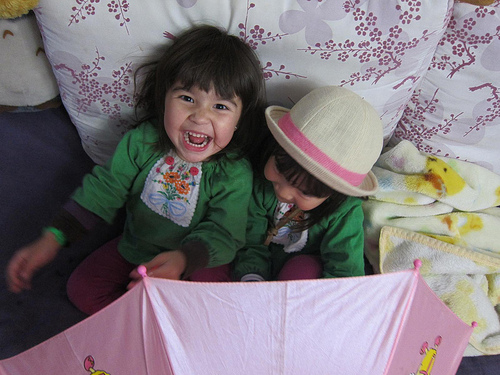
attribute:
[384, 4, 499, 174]
pillow — white, purple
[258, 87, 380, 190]
hat — white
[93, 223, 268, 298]
pants — pink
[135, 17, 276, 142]
hair — dark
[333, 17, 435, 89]
designs — tree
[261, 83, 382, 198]
hat — pink, beige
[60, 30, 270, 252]
girl — little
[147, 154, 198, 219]
flowers — pink, orange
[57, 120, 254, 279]
shirt — green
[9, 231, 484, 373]
umbrella — pink, open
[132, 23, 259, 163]
hair — long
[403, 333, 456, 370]
design — yellow, pink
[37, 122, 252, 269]
long-sleeve shirt — long sleeved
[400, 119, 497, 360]
blanket — white, yellow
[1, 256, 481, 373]
umbrella — pink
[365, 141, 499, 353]
blanket — crumpled, white, yellow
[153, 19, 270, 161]
hair — black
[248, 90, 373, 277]
girl — little, dark brown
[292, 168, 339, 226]
hair — dark brown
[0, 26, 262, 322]
girl — little, smiling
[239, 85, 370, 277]
girl — little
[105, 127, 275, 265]
shirt — long sleeved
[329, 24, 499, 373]
blanket — yellow, white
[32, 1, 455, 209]
pillow — white, purple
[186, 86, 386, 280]
girl — little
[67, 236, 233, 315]
pants — pink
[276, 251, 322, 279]
pants — pink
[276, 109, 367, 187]
stripe — pink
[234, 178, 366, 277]
shirt — green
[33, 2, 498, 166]
blanket — white, red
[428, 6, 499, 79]
flowers — purple, stitched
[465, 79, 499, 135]
flowers — purple, stitched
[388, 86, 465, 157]
flowers — purple, stitched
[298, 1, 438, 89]
flowers — purple, stitched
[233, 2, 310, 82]
flowers — purple, stitched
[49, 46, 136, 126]
flowers — purple, stitched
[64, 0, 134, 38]
flowers — purple, stitched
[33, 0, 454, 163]
pillow — white